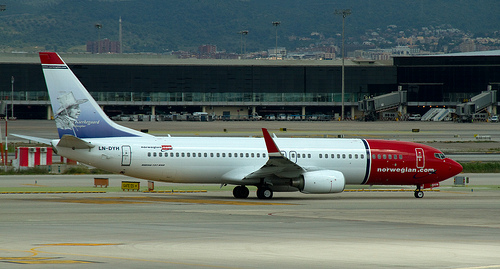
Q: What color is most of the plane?
A: White.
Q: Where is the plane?
A: On the runway.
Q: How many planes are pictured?
A: 1.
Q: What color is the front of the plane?
A: Red.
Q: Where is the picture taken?
A: Airpoort.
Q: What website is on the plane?
A: Norwegian.com.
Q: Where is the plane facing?
A: Right.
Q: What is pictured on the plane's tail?
A: Man with hat.